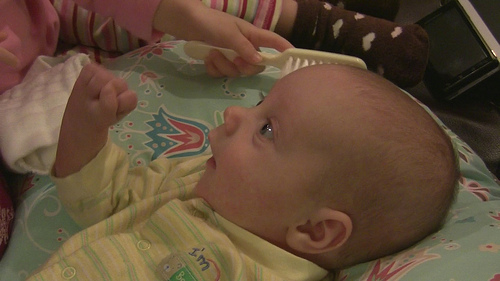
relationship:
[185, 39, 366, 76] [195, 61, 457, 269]
brush on top of head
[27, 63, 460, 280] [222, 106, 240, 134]
baby has nose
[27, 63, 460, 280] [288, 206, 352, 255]
baby has ear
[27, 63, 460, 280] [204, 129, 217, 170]
baby has mouth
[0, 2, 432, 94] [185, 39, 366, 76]
kid holding brush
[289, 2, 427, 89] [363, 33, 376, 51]
sock has heart